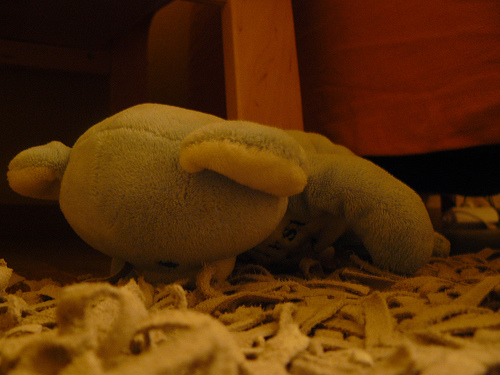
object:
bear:
[9, 101, 449, 278]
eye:
[156, 260, 179, 273]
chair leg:
[223, 0, 306, 130]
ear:
[181, 119, 313, 199]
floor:
[0, 188, 500, 375]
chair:
[228, 0, 500, 154]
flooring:
[194, 288, 285, 320]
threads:
[49, 281, 153, 358]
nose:
[146, 257, 239, 291]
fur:
[113, 132, 148, 163]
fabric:
[305, 0, 499, 161]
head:
[0, 103, 311, 268]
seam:
[71, 124, 186, 145]